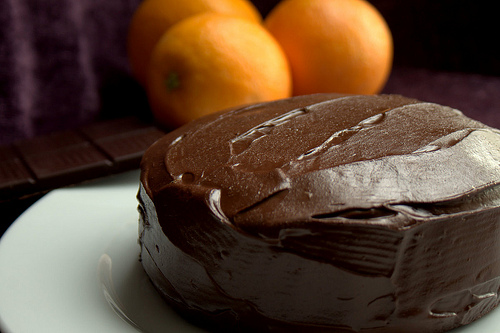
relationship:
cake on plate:
[135, 84, 497, 331] [6, 179, 187, 331]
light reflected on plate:
[98, 245, 125, 319] [100, 213, 148, 330]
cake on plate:
[135, 84, 497, 331] [1, 169, 499, 331]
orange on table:
[128, 0, 265, 83] [4, 108, 152, 210]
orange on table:
[146, 9, 296, 131] [4, 108, 152, 210]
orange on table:
[146, 9, 296, 131] [1, 62, 496, 329]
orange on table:
[264, 0, 395, 94] [1, 62, 496, 329]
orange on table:
[128, 0, 265, 83] [1, 62, 496, 329]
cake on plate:
[135, 84, 497, 331] [2, 89, 497, 329]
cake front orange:
[135, 84, 497, 331] [146, 9, 296, 131]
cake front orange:
[135, 84, 497, 331] [264, 0, 395, 94]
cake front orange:
[135, 84, 497, 331] [128, 0, 265, 83]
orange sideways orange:
[264, 0, 394, 99] [146, 9, 289, 127]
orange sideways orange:
[264, 0, 394, 99] [128, 0, 265, 83]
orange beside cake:
[264, 0, 394, 99] [135, 84, 497, 331]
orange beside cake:
[146, 9, 289, 127] [135, 84, 497, 331]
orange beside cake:
[128, 0, 265, 83] [135, 84, 497, 331]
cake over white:
[135, 84, 497, 331] [0, 200, 134, 333]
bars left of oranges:
[1, 115, 141, 187] [125, 2, 406, 105]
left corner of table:
[29, 165, 107, 231] [4, 1, 153, 134]